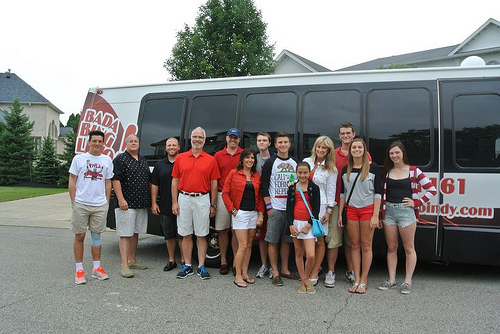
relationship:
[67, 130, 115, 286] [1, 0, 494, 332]
boy posing for picture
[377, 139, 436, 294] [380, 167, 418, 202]
girl wearing tank top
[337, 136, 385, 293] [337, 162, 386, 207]
girl wearing shirt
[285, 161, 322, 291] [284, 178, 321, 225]
girl wearing jacket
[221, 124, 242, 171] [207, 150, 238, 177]
man wearing shirt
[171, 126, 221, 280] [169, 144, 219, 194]
man wearing shirt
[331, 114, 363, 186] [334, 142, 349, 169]
man wearing shirt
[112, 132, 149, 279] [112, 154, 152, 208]
man wearing shirt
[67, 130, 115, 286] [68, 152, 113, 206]
boy wearing shirt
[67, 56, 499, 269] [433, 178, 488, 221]
bus with writing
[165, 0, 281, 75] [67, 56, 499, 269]
tall tree behind bus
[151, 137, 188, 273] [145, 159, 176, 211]
man wearing shirt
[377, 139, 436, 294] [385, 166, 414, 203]
girl wearing black tank-top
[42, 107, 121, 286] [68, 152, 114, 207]
boy wearing shirt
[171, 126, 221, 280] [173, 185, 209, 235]
man wearing shorts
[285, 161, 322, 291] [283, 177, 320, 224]
girl wearing sweater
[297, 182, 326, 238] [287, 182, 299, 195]
handbag on shoulder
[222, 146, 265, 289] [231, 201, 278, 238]
girl wearing shorts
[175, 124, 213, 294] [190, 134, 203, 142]
man wearing eyeglasses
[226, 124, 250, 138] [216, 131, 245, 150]
hat on head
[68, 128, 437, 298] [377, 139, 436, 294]
group of girl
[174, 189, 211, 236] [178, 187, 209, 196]
shorts with a belt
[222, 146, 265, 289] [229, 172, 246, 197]
girl wearing red jacket